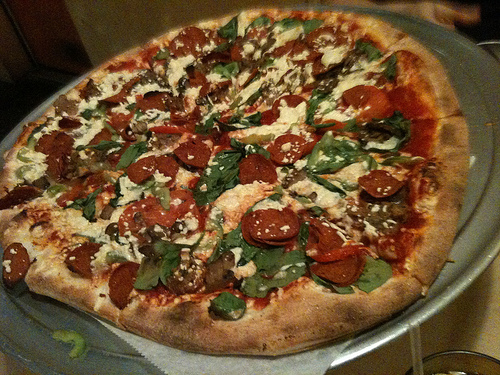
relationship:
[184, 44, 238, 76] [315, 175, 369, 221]
pizza has toppings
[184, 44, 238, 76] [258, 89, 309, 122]
pizza has cheese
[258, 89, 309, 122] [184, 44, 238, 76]
cheese on pizza